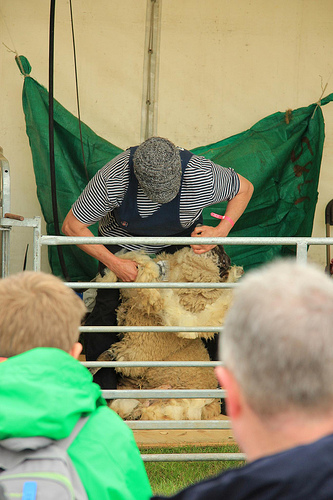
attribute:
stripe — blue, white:
[179, 177, 215, 182]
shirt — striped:
[75, 145, 241, 233]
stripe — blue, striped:
[180, 205, 200, 214]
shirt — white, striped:
[67, 148, 246, 253]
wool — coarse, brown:
[87, 234, 269, 305]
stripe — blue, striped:
[106, 166, 126, 181]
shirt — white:
[71, 139, 239, 265]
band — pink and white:
[206, 210, 238, 226]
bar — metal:
[280, 237, 319, 248]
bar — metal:
[39, 230, 299, 252]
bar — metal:
[296, 222, 308, 263]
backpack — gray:
[2, 438, 105, 497]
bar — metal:
[66, 277, 235, 291]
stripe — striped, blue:
[105, 219, 119, 232]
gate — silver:
[32, 229, 330, 463]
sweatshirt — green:
[19, 356, 95, 409]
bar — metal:
[78, 348, 235, 370]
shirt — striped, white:
[66, 161, 227, 235]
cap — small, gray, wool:
[131, 134, 185, 205]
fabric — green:
[16, 55, 331, 341]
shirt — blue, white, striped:
[72, 146, 239, 250]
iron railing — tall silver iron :
[0, 216, 331, 462]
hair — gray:
[209, 245, 332, 420]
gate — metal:
[104, 302, 225, 426]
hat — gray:
[132, 135, 180, 203]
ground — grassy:
[147, 433, 230, 498]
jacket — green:
[1, 343, 155, 498]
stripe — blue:
[105, 180, 127, 188]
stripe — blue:
[108, 190, 127, 197]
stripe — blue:
[107, 195, 123, 200]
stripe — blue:
[105, 196, 122, 201]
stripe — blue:
[109, 197, 123, 202]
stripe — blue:
[190, 167, 227, 208]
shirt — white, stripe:
[83, 189, 206, 254]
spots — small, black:
[210, 28, 261, 55]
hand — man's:
[188, 228, 217, 260]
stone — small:
[159, 428, 170, 433]